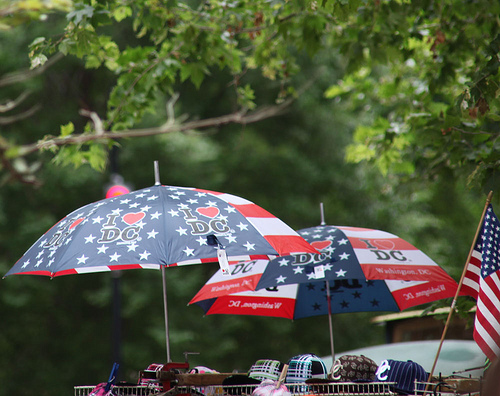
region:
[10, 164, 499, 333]
Patriotic items love DC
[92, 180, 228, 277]
Red hearts white stars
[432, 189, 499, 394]
United States of America flag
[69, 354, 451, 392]
Sale District of Columbia hats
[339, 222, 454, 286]
Washington DC umbrella border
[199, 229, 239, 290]
Price tag side umbrella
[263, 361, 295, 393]
Close pin holds hat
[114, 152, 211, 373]
Umbrella anchored sale cart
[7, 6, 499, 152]
Lush green trees overhead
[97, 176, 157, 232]
Small red bubble top umbrella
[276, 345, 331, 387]
The blue, white and green hat under the middle umbrella.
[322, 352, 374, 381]
The brown and white hat under the umbrella.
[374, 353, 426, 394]
The blue and white striped hat.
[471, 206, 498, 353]
The American flag on the right.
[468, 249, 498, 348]
The stripes on the American flag.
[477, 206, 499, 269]
The stars on the American flag.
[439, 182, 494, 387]
The wooden stick attached to the American flag.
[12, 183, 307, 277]
The DC umbrella on the left.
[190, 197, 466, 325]
The umbrella on the right.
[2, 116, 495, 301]
The trees in the background.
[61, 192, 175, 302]
White stars on umbrella.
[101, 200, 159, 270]
I love DC on umbrella.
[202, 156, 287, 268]
Red and white stripes on umbrella.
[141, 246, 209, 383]
Silver pole on umbrella.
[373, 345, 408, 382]
Blue and white striped hat.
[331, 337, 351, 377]
Brown hat with designs on it.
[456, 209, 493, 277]
American flat in cart.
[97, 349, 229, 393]
Cart holding hats and umbrellas.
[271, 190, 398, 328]
Umbrella next to American flag.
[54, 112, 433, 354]
2 I love DC umbrellas.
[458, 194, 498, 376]
An American Flag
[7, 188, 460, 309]
Two red, white and blue umbrellas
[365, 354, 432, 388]
Blue and white striped hat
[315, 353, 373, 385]
Brown print hat with DC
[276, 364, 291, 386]
A wooden clothes pin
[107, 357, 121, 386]
A blue plastic clothes pin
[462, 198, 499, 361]
A United States flag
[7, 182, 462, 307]
Two umbrellas with stars and stripes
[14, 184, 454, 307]
Two I love DC umbrellas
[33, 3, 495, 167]
Trees with green leaves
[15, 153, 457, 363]
2 umbrellas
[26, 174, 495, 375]
the umbrellas say I love DC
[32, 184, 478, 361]
the umbrellas are red white and blue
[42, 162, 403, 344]
the umbrellas have stars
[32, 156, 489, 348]
the umbrellas are open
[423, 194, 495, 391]
an american flag is next to umbrellas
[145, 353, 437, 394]
hats are in front of umbrellas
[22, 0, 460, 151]
the trees have leaves on them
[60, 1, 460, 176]
the tree's leaves are green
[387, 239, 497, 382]
the flag's handle is brown